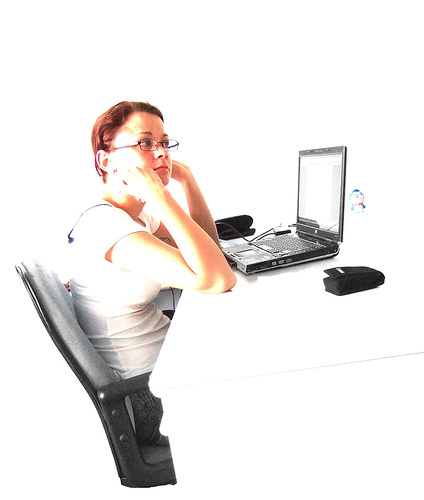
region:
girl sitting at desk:
[29, 94, 242, 387]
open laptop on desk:
[213, 140, 365, 288]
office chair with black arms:
[11, 253, 178, 490]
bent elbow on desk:
[175, 255, 246, 291]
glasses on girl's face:
[132, 133, 200, 159]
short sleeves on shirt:
[95, 202, 167, 281]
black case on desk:
[320, 257, 399, 301]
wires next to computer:
[228, 223, 282, 239]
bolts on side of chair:
[103, 403, 135, 450]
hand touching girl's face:
[117, 165, 166, 198]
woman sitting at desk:
[9, 92, 302, 492]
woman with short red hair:
[62, 90, 244, 463]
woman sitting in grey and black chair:
[11, 97, 249, 490]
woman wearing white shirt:
[48, 92, 250, 456]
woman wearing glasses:
[60, 91, 219, 461]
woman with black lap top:
[210, 139, 357, 285]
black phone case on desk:
[316, 258, 388, 303]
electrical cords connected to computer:
[217, 211, 292, 271]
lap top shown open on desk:
[220, 139, 356, 280]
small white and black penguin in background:
[339, 179, 377, 223]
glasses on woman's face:
[130, 123, 205, 152]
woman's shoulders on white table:
[189, 253, 252, 306]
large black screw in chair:
[81, 382, 120, 405]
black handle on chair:
[89, 373, 177, 403]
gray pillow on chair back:
[13, 248, 113, 380]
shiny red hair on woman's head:
[74, 87, 182, 130]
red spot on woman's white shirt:
[90, 230, 141, 274]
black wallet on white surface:
[310, 258, 385, 305]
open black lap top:
[225, 145, 362, 278]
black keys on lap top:
[255, 219, 324, 279]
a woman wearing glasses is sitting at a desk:
[67, 99, 235, 443]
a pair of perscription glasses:
[106, 136, 179, 151]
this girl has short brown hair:
[90, 99, 163, 181]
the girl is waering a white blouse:
[68, 199, 170, 378]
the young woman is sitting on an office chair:
[13, 259, 175, 489]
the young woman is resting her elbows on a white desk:
[147, 228, 421, 496]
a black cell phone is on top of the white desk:
[323, 266, 385, 294]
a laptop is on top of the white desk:
[219, 145, 346, 274]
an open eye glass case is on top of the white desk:
[213, 214, 254, 240]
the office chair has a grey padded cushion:
[13, 257, 176, 487]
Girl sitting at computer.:
[63, 100, 242, 380]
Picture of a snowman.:
[343, 180, 367, 215]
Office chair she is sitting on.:
[8, 252, 177, 479]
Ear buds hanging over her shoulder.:
[69, 197, 112, 245]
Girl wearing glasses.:
[93, 140, 180, 155]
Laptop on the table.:
[218, 143, 345, 282]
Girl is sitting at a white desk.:
[148, 212, 422, 489]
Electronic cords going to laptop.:
[212, 212, 291, 242]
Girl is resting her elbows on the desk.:
[95, 160, 243, 292]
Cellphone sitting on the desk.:
[319, 263, 395, 297]